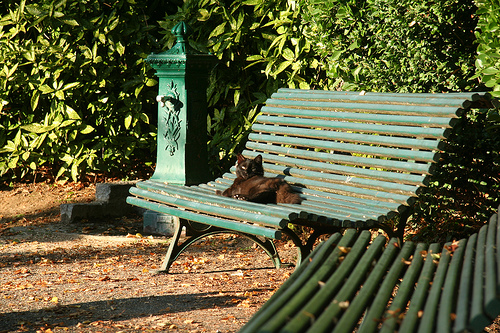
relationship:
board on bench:
[121, 195, 280, 242] [121, 84, 498, 272]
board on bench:
[248, 128, 440, 162] [80, 37, 499, 289]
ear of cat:
[254, 152, 267, 162] [218, 149, 302, 205]